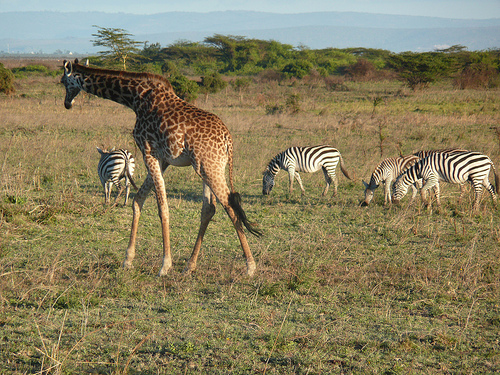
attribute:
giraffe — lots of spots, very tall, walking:
[57, 56, 264, 281]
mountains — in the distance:
[1, 9, 498, 54]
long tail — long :
[488, 156, 499, 198]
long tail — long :
[335, 150, 352, 182]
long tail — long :
[121, 159, 139, 194]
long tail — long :
[222, 134, 269, 241]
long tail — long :
[428, 160, 446, 190]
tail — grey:
[338, 156, 349, 179]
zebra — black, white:
[259, 145, 351, 199]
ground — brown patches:
[295, 213, 498, 373]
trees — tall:
[1, 22, 498, 104]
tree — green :
[87, 23, 149, 71]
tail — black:
[222, 130, 265, 239]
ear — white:
[353, 178, 372, 190]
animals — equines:
[259, 147, 350, 198]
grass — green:
[20, 65, 498, 374]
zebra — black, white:
[255, 141, 352, 200]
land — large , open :
[2, 47, 499, 373]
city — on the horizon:
[0, 45, 94, 57]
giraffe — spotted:
[72, 56, 271, 285]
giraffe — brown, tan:
[35, 16, 302, 333]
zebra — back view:
[88, 136, 148, 205]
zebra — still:
[263, 145, 346, 195]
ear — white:
[61, 58, 74, 75]